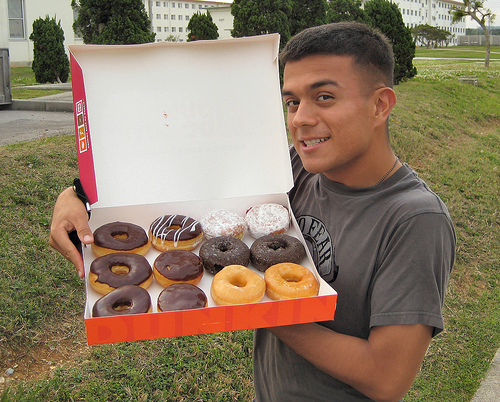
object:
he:
[252, 21, 457, 402]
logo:
[295, 214, 341, 284]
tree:
[447, 0, 497, 69]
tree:
[411, 21, 455, 49]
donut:
[91, 220, 151, 257]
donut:
[148, 213, 203, 252]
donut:
[265, 262, 320, 301]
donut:
[210, 263, 266, 306]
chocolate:
[150, 214, 199, 241]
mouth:
[298, 133, 331, 152]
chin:
[300, 158, 337, 174]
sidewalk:
[470, 348, 500, 401]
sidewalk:
[12, 81, 75, 103]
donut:
[155, 280, 207, 311]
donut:
[199, 235, 250, 274]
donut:
[250, 235, 307, 272]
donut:
[153, 248, 204, 288]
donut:
[89, 251, 153, 295]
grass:
[384, 44, 499, 402]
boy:
[47, 23, 454, 401]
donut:
[201, 208, 248, 241]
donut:
[244, 202, 291, 239]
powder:
[209, 224, 218, 233]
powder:
[277, 208, 282, 216]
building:
[143, 0, 480, 48]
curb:
[8, 98, 74, 115]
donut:
[92, 285, 152, 318]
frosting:
[150, 212, 199, 248]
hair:
[280, 19, 397, 93]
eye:
[315, 93, 336, 104]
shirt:
[255, 145, 456, 400]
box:
[64, 33, 338, 348]